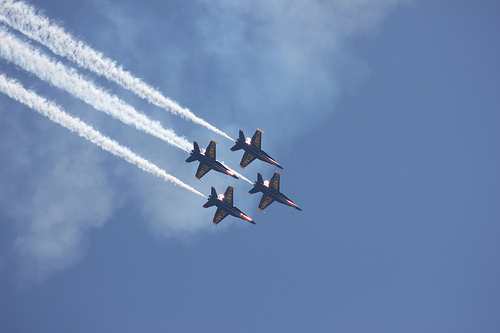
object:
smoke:
[0, 1, 182, 199]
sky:
[420, 62, 497, 126]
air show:
[5, 1, 307, 230]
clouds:
[21, 25, 141, 153]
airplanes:
[247, 171, 302, 215]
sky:
[379, 192, 500, 282]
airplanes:
[181, 140, 240, 182]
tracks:
[0, 0, 188, 195]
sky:
[201, 5, 313, 98]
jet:
[230, 128, 282, 169]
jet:
[203, 185, 256, 227]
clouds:
[200, 25, 315, 72]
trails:
[2, 74, 204, 195]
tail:
[248, 171, 265, 195]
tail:
[230, 128, 246, 152]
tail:
[184, 140, 201, 164]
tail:
[201, 184, 219, 208]